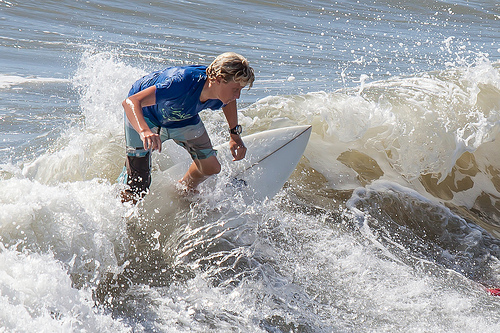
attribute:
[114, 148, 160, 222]
leg — here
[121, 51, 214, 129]
shirt — here, blue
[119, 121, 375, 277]
surfboard — white, here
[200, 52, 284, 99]
hair — blonde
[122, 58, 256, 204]
surfer — white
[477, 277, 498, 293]
object — red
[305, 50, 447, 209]
wave — ridden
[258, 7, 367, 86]
water — very clean, splashing, big, brown, calm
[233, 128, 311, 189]
line — here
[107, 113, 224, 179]
shortsa — here